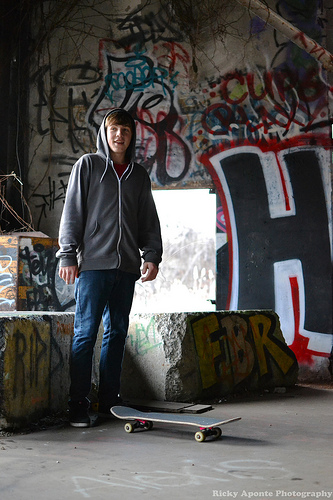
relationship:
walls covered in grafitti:
[90, 44, 330, 268] [203, 168, 324, 381]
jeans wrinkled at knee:
[69, 268, 140, 405] [70, 334, 92, 367]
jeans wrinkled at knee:
[69, 268, 140, 405] [100, 321, 132, 354]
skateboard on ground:
[110, 391, 270, 464] [86, 428, 262, 497]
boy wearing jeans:
[68, 93, 154, 404] [74, 270, 121, 412]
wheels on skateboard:
[123, 421, 132, 433] [109, 399, 239, 442]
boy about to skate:
[56, 106, 164, 429] [45, 95, 244, 449]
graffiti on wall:
[120, 41, 321, 156] [170, 305, 297, 400]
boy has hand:
[56, 106, 164, 429] [139, 262, 158, 281]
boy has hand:
[56, 106, 164, 429] [58, 264, 78, 284]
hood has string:
[93, 103, 136, 159] [98, 153, 111, 183]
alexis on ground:
[55, 455, 297, 497] [55, 414, 327, 489]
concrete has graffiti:
[132, 308, 297, 402] [186, 317, 293, 387]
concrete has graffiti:
[0, 0, 333, 424] [1, 318, 63, 414]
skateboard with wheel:
[110, 406, 242, 444] [123, 421, 132, 432]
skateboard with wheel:
[110, 406, 242, 444] [143, 420, 153, 429]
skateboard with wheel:
[110, 406, 242, 444] [193, 430, 203, 441]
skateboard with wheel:
[110, 406, 242, 444] [211, 425, 222, 437]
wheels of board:
[116, 423, 233, 445] [105, 391, 245, 425]